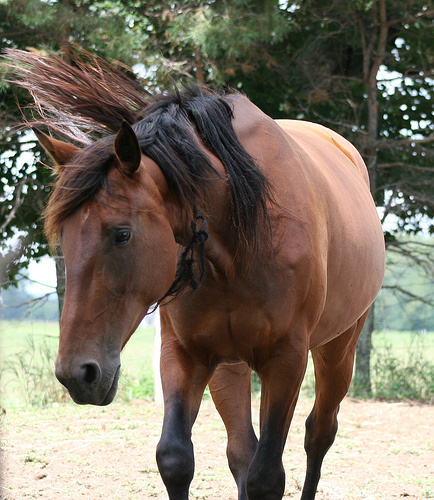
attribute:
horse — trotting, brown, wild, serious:
[30, 91, 387, 500]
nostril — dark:
[81, 363, 96, 386]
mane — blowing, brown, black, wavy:
[2, 37, 276, 260]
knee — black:
[158, 441, 192, 491]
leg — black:
[157, 307, 214, 500]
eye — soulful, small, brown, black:
[114, 228, 133, 243]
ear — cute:
[112, 121, 143, 178]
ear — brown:
[32, 128, 84, 171]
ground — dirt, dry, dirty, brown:
[2, 323, 434, 500]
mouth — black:
[102, 366, 119, 406]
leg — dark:
[241, 346, 308, 500]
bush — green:
[372, 347, 434, 403]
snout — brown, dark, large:
[54, 345, 121, 407]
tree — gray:
[352, 2, 393, 392]